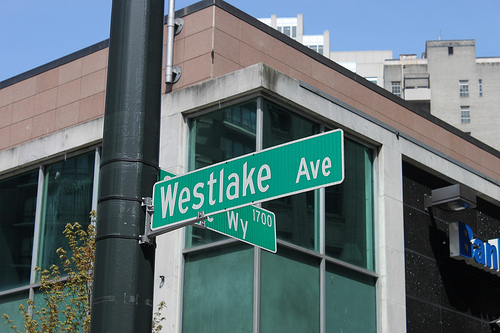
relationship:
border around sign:
[162, 175, 181, 180] [156, 123, 351, 224]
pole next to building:
[97, 1, 155, 332] [168, 4, 491, 332]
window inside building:
[3, 153, 96, 282] [168, 4, 491, 332]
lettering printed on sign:
[294, 156, 332, 183] [156, 123, 351, 224]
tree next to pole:
[21, 222, 93, 333] [97, 1, 155, 332]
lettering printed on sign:
[159, 161, 282, 210] [156, 123, 351, 224]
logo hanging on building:
[452, 220, 497, 270] [168, 4, 491, 332]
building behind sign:
[168, 4, 491, 332] [233, 209, 279, 249]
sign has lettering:
[156, 123, 351, 224] [294, 156, 332, 183]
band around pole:
[100, 157, 165, 167] [97, 1, 155, 332]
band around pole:
[94, 192, 143, 204] [97, 1, 155, 332]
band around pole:
[92, 226, 137, 243] [97, 1, 155, 332]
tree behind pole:
[21, 222, 93, 333] [97, 1, 155, 332]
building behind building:
[168, 4, 491, 332] [168, 4, 491, 332]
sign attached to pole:
[156, 123, 351, 224] [97, 1, 155, 332]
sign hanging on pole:
[156, 123, 351, 224] [97, 1, 155, 332]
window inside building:
[190, 108, 259, 148] [168, 4, 491, 332]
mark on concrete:
[179, 82, 215, 95] [184, 61, 323, 97]